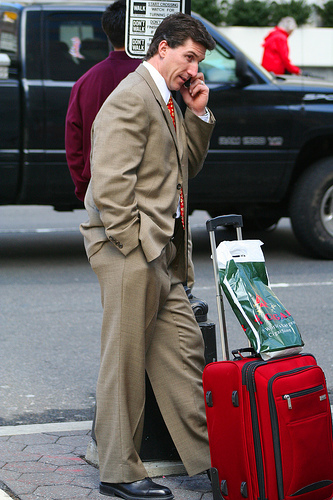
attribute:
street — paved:
[0, 204, 332, 425]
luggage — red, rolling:
[198, 213, 332, 497]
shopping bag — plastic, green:
[209, 237, 305, 362]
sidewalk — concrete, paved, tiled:
[1, 423, 215, 499]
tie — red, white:
[164, 94, 185, 229]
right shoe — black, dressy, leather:
[98, 475, 175, 499]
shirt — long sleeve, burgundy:
[64, 49, 142, 204]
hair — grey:
[274, 14, 297, 37]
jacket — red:
[259, 25, 299, 75]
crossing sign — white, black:
[120, 0, 186, 65]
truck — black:
[1, 2, 332, 263]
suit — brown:
[79, 65, 215, 485]